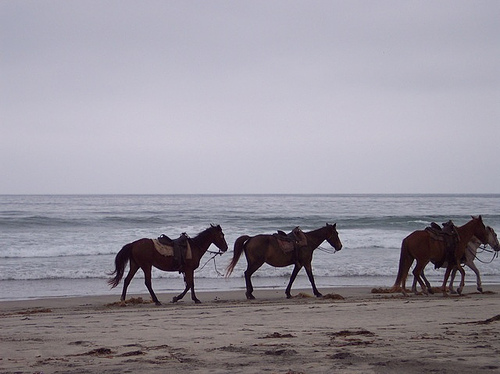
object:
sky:
[1, 0, 499, 192]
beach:
[0, 282, 499, 371]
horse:
[227, 223, 342, 303]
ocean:
[2, 195, 500, 279]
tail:
[224, 234, 250, 276]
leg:
[303, 259, 323, 297]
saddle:
[270, 229, 309, 254]